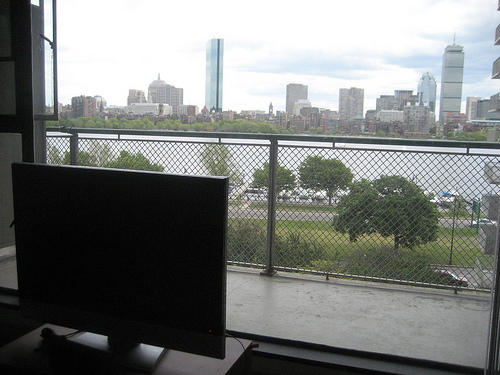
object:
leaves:
[346, 208, 375, 230]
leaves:
[333, 165, 350, 182]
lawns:
[296, 216, 366, 251]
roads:
[228, 189, 333, 226]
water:
[307, 143, 457, 223]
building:
[441, 27, 468, 110]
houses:
[421, 120, 437, 132]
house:
[144, 73, 170, 90]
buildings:
[403, 105, 428, 132]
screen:
[6, 157, 243, 368]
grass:
[228, 200, 498, 284]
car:
[426, 258, 471, 292]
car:
[468, 212, 499, 234]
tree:
[63, 96, 488, 178]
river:
[72, 95, 495, 245]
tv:
[11, 161, 228, 373]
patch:
[52, 0, 279, 97]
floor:
[222, 270, 484, 354]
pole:
[263, 137, 278, 287]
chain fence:
[267, 131, 494, 291]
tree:
[327, 174, 439, 254]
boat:
[307, 185, 331, 207]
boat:
[293, 182, 315, 207]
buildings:
[66, 25, 493, 137]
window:
[40, 3, 498, 353]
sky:
[28, 5, 498, 120]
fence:
[34, 120, 498, 304]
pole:
[448, 27, 463, 52]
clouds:
[30, 5, 498, 119]